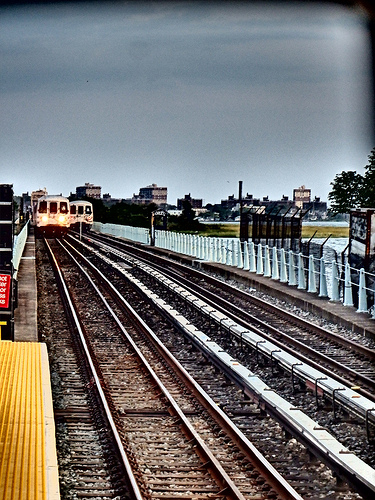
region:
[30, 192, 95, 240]
two trains coming down the tracks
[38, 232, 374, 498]
two sets of train tracks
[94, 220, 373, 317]
white fence near the tracks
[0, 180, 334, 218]
buildings behind the two trains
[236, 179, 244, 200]
smokestack jutting up into the sky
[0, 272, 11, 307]
red sign with white lettering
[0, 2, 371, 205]
stormy and gloomy sky above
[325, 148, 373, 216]
tree with green leaves on the right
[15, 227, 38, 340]
walkway for railroad workers near the tracks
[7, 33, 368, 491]
two trains two tracks two separation rails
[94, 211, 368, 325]
white guard rail next to train track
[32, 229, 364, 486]
gravel bed for two train tracks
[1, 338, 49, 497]
yellow roofing overhang next to tracks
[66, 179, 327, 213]
taller buildings in the background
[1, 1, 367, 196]
sky above two train tracks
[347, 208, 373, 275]
sign with wood frame on the side of tracks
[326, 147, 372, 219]
tree on the side of two tracks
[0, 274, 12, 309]
red bench on the side of train tracks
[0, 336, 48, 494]
yellow grate by track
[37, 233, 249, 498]
train tracks with rocks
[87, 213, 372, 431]
train tracks with rocks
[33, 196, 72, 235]
train on train tracks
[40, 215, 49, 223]
front light of train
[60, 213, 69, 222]
front light of train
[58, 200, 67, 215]
front window of train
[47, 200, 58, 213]
front window of train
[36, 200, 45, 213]
front window of train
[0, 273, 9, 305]
red sign by tracks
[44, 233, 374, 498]
two tracks for electric trains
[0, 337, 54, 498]
yellow non slip platform for train boarding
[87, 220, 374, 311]
a white railing along the train tracks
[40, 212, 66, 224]
headlights of an approaching train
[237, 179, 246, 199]
a tall chimney in the distance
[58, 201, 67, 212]
operatooooooor is visible in the front window of the train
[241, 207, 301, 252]
tall black chain link fence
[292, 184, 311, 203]
a billboard sign stands above the buildings nearby it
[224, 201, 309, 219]
homes mixed within trees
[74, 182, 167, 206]
twin larger commercial buildings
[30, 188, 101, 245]
Trains on the tracks.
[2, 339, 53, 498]
yellow coloring on the platform.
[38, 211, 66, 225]
Headlights on the train.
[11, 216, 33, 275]
White railing beside the tracks.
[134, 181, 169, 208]
Building in the background.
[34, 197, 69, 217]
Windows on the train.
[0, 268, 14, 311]
Red sign beside the tracks.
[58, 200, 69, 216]
Person on the train.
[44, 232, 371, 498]
Tracks on the ground.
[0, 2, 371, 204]
blue sky in the background.